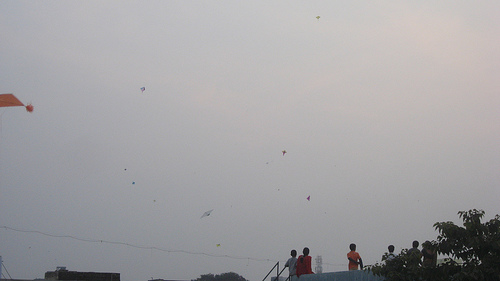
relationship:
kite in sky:
[139, 85, 146, 92] [0, 1, 500, 279]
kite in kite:
[0, 92, 33, 112] [197, 208, 213, 220]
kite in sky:
[196, 205, 218, 223] [178, 44, 463, 130]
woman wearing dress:
[296, 241, 311, 271] [296, 247, 313, 272]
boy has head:
[345, 232, 364, 269] [346, 240, 358, 251]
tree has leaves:
[425, 200, 497, 250] [406, 216, 484, 258]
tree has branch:
[425, 200, 497, 250] [413, 209, 491, 250]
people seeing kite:
[281, 238, 445, 279] [0, 90, 37, 114]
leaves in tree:
[432, 210, 499, 272] [367, 203, 499, 279]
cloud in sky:
[0, 0, 500, 281] [0, 1, 500, 279]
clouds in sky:
[219, 15, 493, 169] [0, 1, 500, 279]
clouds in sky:
[278, 40, 480, 222] [173, 50, 496, 200]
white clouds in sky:
[368, 77, 433, 120] [93, 17, 485, 237]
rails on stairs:
[258, 257, 309, 279] [262, 255, 296, 278]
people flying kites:
[373, 226, 440, 278] [239, 117, 330, 218]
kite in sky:
[305, 192, 312, 200] [0, 1, 500, 279]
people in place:
[253, 219, 453, 279] [252, 220, 426, 276]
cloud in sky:
[75, 17, 455, 227] [170, 24, 370, 164]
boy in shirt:
[346, 242, 363, 270] [348, 251, 368, 274]